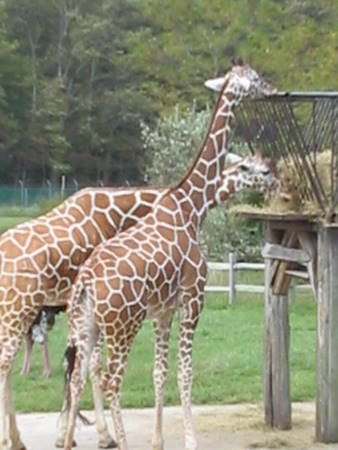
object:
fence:
[0, 174, 78, 214]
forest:
[0, 1, 338, 183]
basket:
[233, 84, 338, 224]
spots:
[231, 82, 246, 93]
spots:
[101, 257, 120, 277]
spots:
[239, 172, 267, 189]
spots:
[254, 80, 267, 92]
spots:
[82, 270, 98, 295]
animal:
[58, 65, 277, 450]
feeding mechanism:
[231, 92, 338, 215]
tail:
[68, 285, 79, 349]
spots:
[108, 282, 132, 311]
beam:
[264, 222, 292, 432]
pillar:
[260, 225, 294, 431]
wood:
[260, 224, 336, 443]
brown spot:
[10, 227, 45, 254]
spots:
[180, 189, 193, 230]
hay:
[226, 150, 335, 220]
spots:
[114, 253, 164, 281]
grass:
[1, 293, 332, 410]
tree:
[139, 102, 271, 263]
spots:
[92, 193, 114, 216]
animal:
[1, 154, 280, 450]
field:
[1, 201, 336, 405]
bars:
[229, 102, 328, 206]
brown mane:
[154, 71, 230, 212]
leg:
[177, 292, 203, 428]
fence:
[207, 251, 316, 301]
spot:
[149, 270, 169, 290]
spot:
[128, 253, 150, 278]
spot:
[131, 278, 146, 294]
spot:
[119, 278, 137, 302]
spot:
[144, 303, 168, 315]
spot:
[116, 260, 136, 277]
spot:
[95, 251, 113, 262]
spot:
[103, 241, 126, 257]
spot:
[98, 301, 113, 313]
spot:
[140, 241, 155, 253]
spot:
[118, 236, 141, 251]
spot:
[139, 225, 154, 236]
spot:
[115, 233, 134, 239]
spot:
[153, 249, 166, 263]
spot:
[177, 262, 196, 292]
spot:
[198, 262, 209, 276]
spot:
[175, 228, 193, 254]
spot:
[162, 242, 171, 257]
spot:
[85, 220, 100, 248]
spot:
[72, 224, 88, 252]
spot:
[69, 206, 84, 222]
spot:
[50, 215, 75, 227]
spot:
[55, 201, 66, 212]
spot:
[13, 229, 31, 247]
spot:
[0, 260, 16, 277]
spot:
[0, 271, 17, 292]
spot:
[31, 248, 49, 271]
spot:
[14, 221, 28, 230]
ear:
[253, 79, 278, 97]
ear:
[205, 77, 227, 94]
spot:
[169, 240, 186, 268]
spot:
[161, 240, 169, 255]